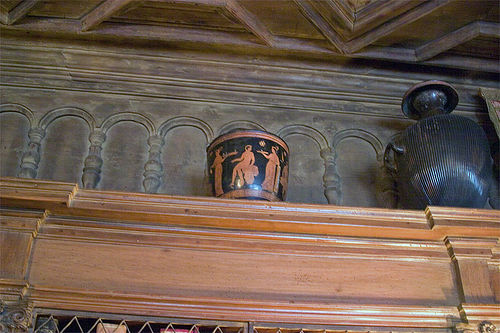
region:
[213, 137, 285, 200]
image of people on side of vase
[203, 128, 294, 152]
clay colored striped border at top of vase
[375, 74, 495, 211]
black vase at top of wooden ledge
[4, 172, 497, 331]
wooden ledge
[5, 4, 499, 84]
ornate wooden ceiling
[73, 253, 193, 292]
striation marks in wood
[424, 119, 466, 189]
line textured pattern on surface of vase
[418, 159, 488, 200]
light refelcting on black vase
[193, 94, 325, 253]
This is a pot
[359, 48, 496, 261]
This is a pot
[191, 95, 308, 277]
This is a pot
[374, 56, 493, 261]
This is a pot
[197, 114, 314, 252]
This is a pot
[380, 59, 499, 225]
This is a pot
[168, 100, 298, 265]
This is a pot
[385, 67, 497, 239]
This is a pot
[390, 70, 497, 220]
This is a pot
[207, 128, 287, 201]
a piece of ancient pottery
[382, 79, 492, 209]
a piece of dark pottery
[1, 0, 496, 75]
ornate, ridged ceiling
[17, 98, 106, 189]
an archway decorating the wall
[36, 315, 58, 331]
the dark spine of a book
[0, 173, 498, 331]
the wood from a bookcase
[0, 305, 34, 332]
the ornately decorated corner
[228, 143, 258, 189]
a drawing of a sitting person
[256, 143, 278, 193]
the drawing of a person holding a tray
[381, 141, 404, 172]
the handle on a piece of pottery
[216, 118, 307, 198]
black and brown urn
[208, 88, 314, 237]
urn on mantle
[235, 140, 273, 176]
people printed on urn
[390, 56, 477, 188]
large black urn on mantle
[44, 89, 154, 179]
dirty grey stone above mantle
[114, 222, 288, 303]
wood on the mantle piece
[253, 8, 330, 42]
wooden beams on ceiling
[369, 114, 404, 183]
black handle on side of urn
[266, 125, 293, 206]
brown pictures on urn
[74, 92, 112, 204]
scroll on decorative wall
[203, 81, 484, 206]
pottery pieces on shelf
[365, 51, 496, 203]
dark colored vase on shelf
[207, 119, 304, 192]
bowl on the shelf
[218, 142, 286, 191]
figures on the bowl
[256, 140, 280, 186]
female on the bowl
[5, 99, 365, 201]
arched patterns against the wall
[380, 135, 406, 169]
handle on dark vase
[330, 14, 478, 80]
pattern on the ceiling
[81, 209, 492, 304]
wood of the shelf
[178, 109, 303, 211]
a round vase on a shelf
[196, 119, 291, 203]
pictures on the vase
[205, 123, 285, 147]
orange trim on top of vase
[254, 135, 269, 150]
orange dot on the vase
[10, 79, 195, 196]
arches on the wall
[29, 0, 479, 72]
design on the ceiling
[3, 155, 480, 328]
a wooden brown shelf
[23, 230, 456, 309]
A piece of wood.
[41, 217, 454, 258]
A piece of wood.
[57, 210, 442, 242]
A piece of wood.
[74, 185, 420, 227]
A piece of wood.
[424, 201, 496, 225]
A piece of wood.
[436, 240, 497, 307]
A piece of wood.